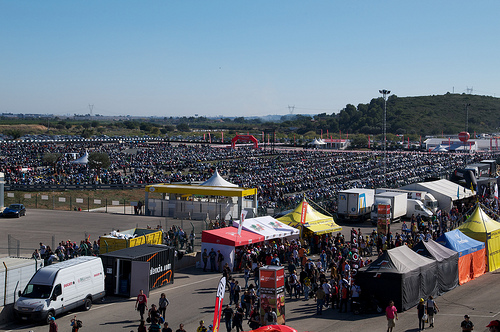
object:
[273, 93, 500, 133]
hill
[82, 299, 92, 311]
tire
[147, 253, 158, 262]
stripe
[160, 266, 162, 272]
letters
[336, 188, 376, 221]
truck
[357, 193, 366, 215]
design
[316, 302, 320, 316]
leg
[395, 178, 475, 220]
tent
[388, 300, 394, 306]
head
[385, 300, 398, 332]
person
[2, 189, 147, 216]
white signs/fence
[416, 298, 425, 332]
person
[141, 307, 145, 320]
leg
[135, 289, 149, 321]
person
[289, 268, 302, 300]
person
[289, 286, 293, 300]
leg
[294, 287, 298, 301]
leg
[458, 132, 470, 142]
balloon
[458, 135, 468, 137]
stripe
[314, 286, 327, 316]
person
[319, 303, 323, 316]
leg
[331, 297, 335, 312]
leg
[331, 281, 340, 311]
person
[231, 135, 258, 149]
arche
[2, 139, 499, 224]
lot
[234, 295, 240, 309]
leg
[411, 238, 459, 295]
black tent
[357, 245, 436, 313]
black tent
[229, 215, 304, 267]
tent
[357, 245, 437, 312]
tent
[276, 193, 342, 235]
tent top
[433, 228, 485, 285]
tent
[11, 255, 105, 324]
van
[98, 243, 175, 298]
trailer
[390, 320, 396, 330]
leg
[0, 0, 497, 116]
sky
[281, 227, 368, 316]
crowd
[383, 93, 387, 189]
light pole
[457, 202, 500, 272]
tent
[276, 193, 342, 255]
tent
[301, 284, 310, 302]
leg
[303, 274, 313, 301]
person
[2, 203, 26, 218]
car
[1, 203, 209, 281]
parking lot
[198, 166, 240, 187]
tent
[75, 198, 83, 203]
sign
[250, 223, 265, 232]
logos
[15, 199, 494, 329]
road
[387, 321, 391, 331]
leg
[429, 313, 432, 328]
leg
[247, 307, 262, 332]
person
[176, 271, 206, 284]
part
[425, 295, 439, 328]
people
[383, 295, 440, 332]
walking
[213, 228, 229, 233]
part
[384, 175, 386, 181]
part